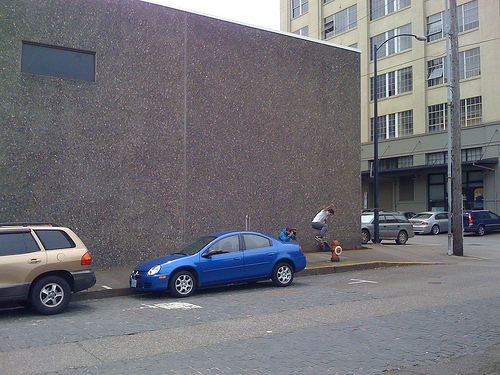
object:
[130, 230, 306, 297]
car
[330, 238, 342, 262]
hydrant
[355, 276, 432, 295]
asphalt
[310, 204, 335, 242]
person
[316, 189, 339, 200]
air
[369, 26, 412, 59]
window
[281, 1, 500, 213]
building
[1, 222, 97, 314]
suv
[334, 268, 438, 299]
street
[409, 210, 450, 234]
car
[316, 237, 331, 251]
skateboard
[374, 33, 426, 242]
lamppost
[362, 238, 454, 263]
corner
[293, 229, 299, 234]
camera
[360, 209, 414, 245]
car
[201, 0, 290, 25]
sky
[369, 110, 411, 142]
window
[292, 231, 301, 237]
photograph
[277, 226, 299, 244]
cameraman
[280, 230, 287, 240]
blue